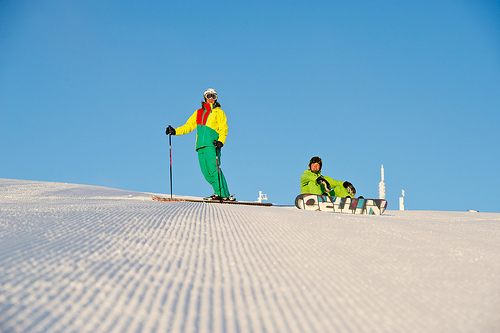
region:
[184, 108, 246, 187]
the clothes are green and yellow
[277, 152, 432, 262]
the person is sitting on the snow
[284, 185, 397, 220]
the skate board has graffiti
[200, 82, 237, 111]
the guy has a white helmet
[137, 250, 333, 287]
the ground has snow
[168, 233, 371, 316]
there is ski tracks on the snow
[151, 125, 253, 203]
the person is holding two skis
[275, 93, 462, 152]
the sky is cloudless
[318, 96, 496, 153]
the sky is blue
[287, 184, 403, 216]
the skate bord is lying on one side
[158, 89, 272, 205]
a person is skiing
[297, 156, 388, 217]
a person is snowboarding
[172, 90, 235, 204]
the person is standing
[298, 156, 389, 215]
the person is sitting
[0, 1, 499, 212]
the sky is blue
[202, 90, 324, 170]
the men wear helmets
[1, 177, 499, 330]
the snow has tracks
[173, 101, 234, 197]
the man has a red yellow and green suit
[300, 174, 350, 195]
the man has a green jacket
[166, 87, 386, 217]
the men are on the snow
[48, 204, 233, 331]
Grooves in the snow.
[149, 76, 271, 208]
A skier standing on the slope.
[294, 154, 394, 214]
A person sitting on the snow.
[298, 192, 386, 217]
A word "Cellin" displayed.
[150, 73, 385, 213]
Two people posing for the cameras.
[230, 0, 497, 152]
A clear blue sky.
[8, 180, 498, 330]
A snow covered slope.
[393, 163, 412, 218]
A creation made from the snow.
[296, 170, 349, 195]
The person's lime green ensemble.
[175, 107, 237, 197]
The skier's yellow and green ensemble.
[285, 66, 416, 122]
Sky is blue color.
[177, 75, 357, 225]
Two people are seen.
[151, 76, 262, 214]
One person holding skiing poles in hand.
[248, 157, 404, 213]
Three white poles are seen.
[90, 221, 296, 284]
Ground is white color.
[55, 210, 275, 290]
Snow is in ground.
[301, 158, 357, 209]
One man is sitting in snow.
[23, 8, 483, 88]
Sky is clear without clouds.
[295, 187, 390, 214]
One snowboard is seen.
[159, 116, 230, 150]
Gloves is black color.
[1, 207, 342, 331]
freshly manicured snow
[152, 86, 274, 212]
a woman on skis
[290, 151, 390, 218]
two people sitting near a snowboard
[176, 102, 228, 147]
a green and yellow jacket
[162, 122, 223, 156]
a pair of black gloves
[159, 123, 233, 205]
two ski poles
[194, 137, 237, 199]
a pair of green snow pants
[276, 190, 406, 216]
a snowboard with a brand on it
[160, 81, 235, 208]
a woman with a white helmet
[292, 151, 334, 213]
a person with a dark hat